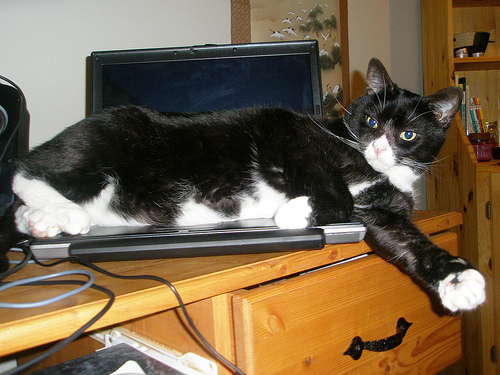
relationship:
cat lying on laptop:
[12, 50, 493, 306] [31, 30, 363, 266]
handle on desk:
[343, 314, 415, 362] [0, 206, 468, 370]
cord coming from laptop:
[0, 248, 250, 373] [31, 30, 363, 266]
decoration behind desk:
[227, 2, 349, 113] [0, 206, 468, 370]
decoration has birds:
[227, 2, 349, 113] [264, 7, 341, 66]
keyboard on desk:
[27, 334, 213, 372] [0, 206, 468, 370]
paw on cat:
[438, 266, 493, 319] [12, 50, 493, 306]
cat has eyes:
[12, 50, 493, 306] [365, 109, 425, 148]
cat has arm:
[12, 50, 493, 306] [358, 190, 498, 319]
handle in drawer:
[348, 314, 418, 367] [234, 223, 478, 372]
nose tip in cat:
[369, 142, 389, 160] [12, 50, 493, 306]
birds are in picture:
[263, 7, 339, 58] [234, 0, 359, 120]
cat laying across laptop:
[12, 50, 493, 306] [31, 30, 363, 266]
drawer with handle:
[218, 231, 467, 371] [341, 312, 418, 366]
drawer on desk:
[218, 231, 467, 371] [0, 206, 468, 370]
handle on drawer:
[343, 314, 415, 362] [218, 231, 467, 371]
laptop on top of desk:
[31, 30, 363, 266] [0, 206, 468, 370]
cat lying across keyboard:
[12, 50, 493, 306] [52, 227, 329, 261]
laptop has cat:
[31, 30, 363, 266] [12, 50, 493, 306]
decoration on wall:
[227, 2, 354, 114] [1, 4, 431, 222]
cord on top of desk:
[0, 248, 250, 373] [0, 206, 468, 370]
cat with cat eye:
[12, 50, 493, 306] [363, 114, 380, 130]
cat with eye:
[12, 50, 493, 306] [393, 125, 419, 145]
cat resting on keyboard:
[12, 50, 493, 306] [56, 224, 326, 263]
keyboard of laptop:
[56, 224, 326, 263] [31, 30, 363, 266]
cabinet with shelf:
[417, 1, 483, 372] [452, 54, 484, 65]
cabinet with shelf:
[417, 1, 483, 372] [466, 145, 484, 167]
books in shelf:
[454, 74, 484, 142] [417, 1, 483, 371]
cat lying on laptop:
[12, 50, 493, 306] [22, 37, 372, 281]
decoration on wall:
[227, 2, 349, 113] [1, 4, 431, 222]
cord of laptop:
[23, 248, 249, 373] [31, 30, 363, 266]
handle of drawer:
[343, 314, 415, 362] [218, 231, 467, 371]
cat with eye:
[12, 50, 493, 306] [361, 113, 384, 132]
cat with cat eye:
[12, 50, 493, 306] [398, 128, 417, 143]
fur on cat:
[27, 109, 428, 248] [0, 51, 485, 326]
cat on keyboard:
[12, 57, 489, 315] [35, 210, 384, 253]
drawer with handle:
[216, 231, 465, 374] [338, 319, 404, 369]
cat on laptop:
[12, 57, 489, 315] [111, 225, 233, 266]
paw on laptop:
[269, 192, 312, 237] [285, 190, 317, 231]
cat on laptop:
[12, 57, 489, 315] [135, 65, 311, 125]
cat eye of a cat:
[363, 114, 380, 130] [12, 50, 493, 306]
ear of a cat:
[362, 55, 399, 100] [12, 50, 493, 306]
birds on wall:
[251, 0, 345, 96] [1, 4, 431, 222]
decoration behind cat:
[227, 2, 349, 113] [12, 50, 493, 306]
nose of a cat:
[368, 133, 390, 157] [12, 50, 493, 306]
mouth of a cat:
[363, 153, 397, 169] [12, 50, 493, 306]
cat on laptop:
[12, 50, 493, 306] [31, 30, 363, 266]